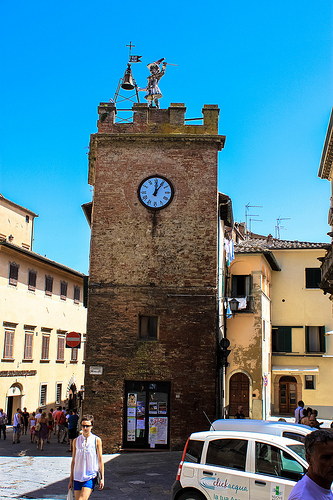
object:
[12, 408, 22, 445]
people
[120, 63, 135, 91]
bell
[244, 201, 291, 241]
antennas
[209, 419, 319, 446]
white car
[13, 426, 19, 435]
shorts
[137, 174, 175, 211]
clock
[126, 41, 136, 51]
cross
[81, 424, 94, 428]
sunglasses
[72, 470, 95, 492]
blue shorts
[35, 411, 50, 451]
woman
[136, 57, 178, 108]
pirate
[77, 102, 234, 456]
building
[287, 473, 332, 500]
t-shirt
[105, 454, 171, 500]
ground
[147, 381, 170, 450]
door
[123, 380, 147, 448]
door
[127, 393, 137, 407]
flyer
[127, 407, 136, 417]
flyer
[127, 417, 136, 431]
flyer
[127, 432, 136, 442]
flyer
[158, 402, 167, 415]
flyer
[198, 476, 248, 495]
name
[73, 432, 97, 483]
white top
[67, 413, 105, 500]
woman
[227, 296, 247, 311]
linen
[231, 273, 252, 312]
window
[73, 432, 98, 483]
shirt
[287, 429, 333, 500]
man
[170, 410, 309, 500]
car